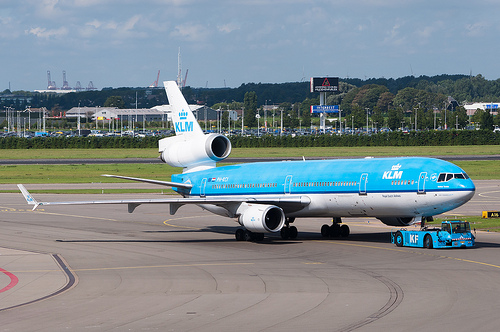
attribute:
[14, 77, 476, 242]
airplane — blue , white 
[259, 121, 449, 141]
parked cars — large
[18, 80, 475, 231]
passenger jet — white , blue 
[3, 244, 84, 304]
stripe — black, curved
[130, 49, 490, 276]
airplane — large 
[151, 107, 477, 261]
plane — blue, white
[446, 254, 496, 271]
line — yellow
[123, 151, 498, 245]
plane — white , blue 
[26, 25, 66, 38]
cloud — white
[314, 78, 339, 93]
sign — lower 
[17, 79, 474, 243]
plane — large , blue, white